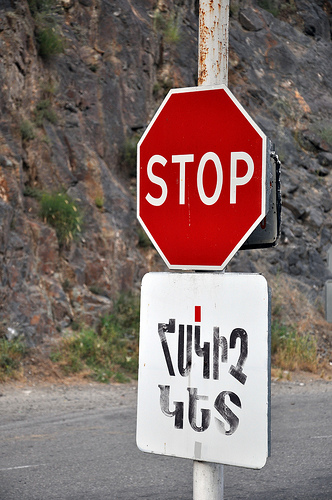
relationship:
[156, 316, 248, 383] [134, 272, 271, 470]
lettering on sign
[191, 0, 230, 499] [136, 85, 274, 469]
pole supports signs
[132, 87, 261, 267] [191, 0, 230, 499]
sign on pole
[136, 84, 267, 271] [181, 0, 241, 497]
sign on pole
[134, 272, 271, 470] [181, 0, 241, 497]
sign on pole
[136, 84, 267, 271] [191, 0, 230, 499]
sign on pole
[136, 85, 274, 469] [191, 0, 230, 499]
signs on pole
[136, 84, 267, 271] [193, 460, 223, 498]
sign on white pole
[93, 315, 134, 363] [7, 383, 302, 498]
grass alongside of road